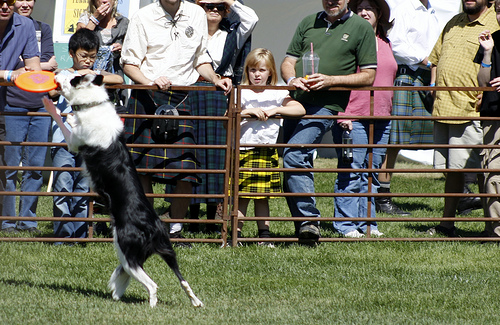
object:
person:
[233, 48, 306, 238]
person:
[277, 0, 379, 238]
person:
[1, 0, 45, 116]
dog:
[41, 70, 204, 307]